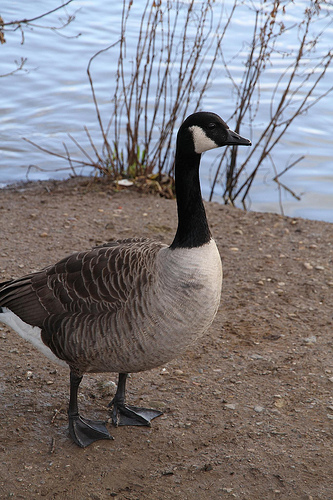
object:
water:
[1, 1, 332, 114]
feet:
[66, 372, 162, 449]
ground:
[1, 178, 332, 500]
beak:
[224, 128, 251, 146]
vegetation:
[240, 0, 283, 103]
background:
[1, 1, 332, 229]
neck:
[175, 149, 212, 251]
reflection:
[273, 178, 303, 202]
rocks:
[315, 265, 324, 271]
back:
[0, 240, 169, 325]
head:
[174, 111, 253, 155]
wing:
[1, 246, 136, 318]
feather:
[35, 287, 58, 304]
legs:
[70, 373, 77, 413]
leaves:
[252, 0, 322, 69]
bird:
[0, 110, 250, 433]